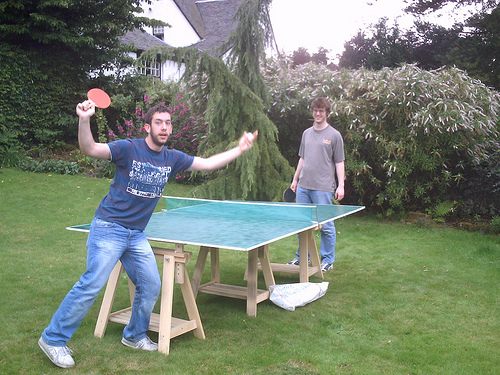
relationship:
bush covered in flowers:
[99, 77, 218, 192] [168, 94, 193, 122]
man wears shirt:
[35, 97, 260, 369] [92, 134, 202, 234]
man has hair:
[290, 93, 355, 280] [304, 91, 331, 112]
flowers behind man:
[137, 71, 209, 105] [35, 97, 260, 369]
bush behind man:
[255, 56, 498, 126] [282, 94, 358, 275]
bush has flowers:
[264, 51, 498, 241] [252, 49, 499, 132]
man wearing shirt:
[35, 97, 260, 369] [92, 134, 192, 233]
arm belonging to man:
[75, 115, 127, 165] [35, 97, 260, 369]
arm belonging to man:
[174, 144, 240, 172] [35, 97, 260, 369]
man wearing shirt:
[290, 93, 355, 280] [295, 121, 345, 191]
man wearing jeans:
[290, 93, 355, 280] [291, 183, 337, 263]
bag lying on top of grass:
[267, 278, 330, 312] [1, 168, 483, 373]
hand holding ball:
[236, 129, 258, 153] [244, 130, 254, 140]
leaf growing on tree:
[46, 107, 50, 114] [1, 1, 154, 150]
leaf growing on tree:
[29, 78, 35, 83] [1, 1, 154, 150]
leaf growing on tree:
[5, 87, 10, 91] [1, 1, 154, 150]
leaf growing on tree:
[26, 60, 31, 64] [1, 1, 154, 150]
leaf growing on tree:
[56, 66, 58, 69] [1, 1, 154, 150]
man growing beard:
[35, 97, 260, 369] [148, 125, 170, 145]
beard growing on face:
[148, 125, 170, 145] [147, 109, 171, 147]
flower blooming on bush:
[383, 91, 393, 99] [257, 49, 484, 226]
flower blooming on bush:
[426, 111, 434, 121] [257, 49, 484, 226]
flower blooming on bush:
[416, 77, 428, 87] [257, 49, 484, 226]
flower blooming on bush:
[336, 81, 345, 90] [257, 49, 484, 226]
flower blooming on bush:
[445, 79, 450, 87] [257, 49, 484, 226]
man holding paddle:
[290, 93, 355, 280] [281, 185, 297, 203]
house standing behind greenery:
[86, 1, 290, 86] [1, 0, 298, 199]